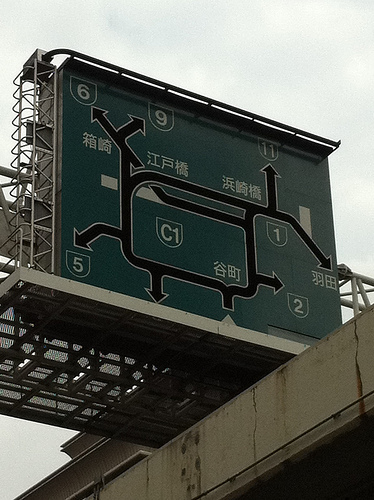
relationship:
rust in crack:
[353, 369, 370, 419] [345, 316, 369, 425]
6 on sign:
[69, 77, 100, 105] [59, 63, 347, 338]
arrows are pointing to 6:
[86, 103, 113, 126] [69, 77, 100, 105]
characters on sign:
[69, 72, 340, 319] [59, 63, 347, 338]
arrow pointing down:
[144, 280, 172, 303] [144, 287, 176, 308]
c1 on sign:
[155, 214, 187, 250] [59, 63, 347, 338]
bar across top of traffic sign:
[43, 46, 341, 149] [59, 63, 347, 338]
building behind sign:
[11, 424, 143, 496] [3, 50, 368, 447]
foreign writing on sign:
[77, 129, 336, 291] [41, 49, 358, 345]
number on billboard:
[285, 297, 317, 317] [59, 63, 347, 338]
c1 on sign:
[155, 214, 187, 250] [41, 49, 358, 345]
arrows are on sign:
[86, 103, 113, 126] [41, 49, 358, 345]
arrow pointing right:
[265, 268, 286, 295] [268, 272, 287, 297]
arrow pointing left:
[67, 225, 96, 253] [67, 228, 94, 253]